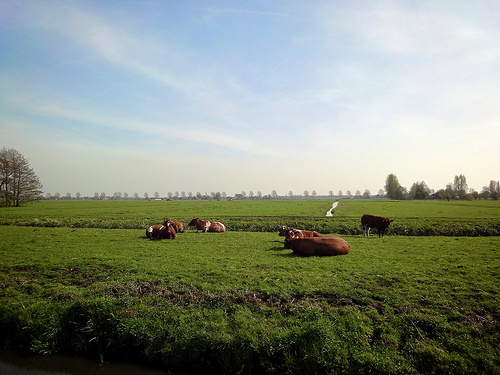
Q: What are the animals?
A: Cows.